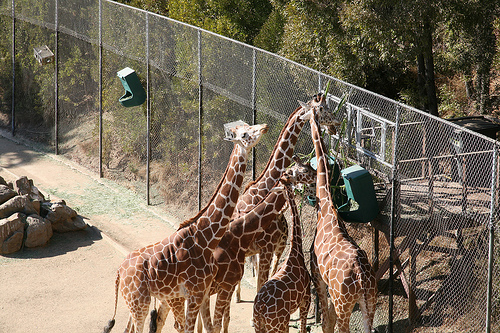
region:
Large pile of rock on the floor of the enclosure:
[0, 172, 97, 252]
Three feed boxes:
[116, 66, 385, 218]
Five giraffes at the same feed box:
[96, 86, 381, 329]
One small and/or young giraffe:
[247, 168, 317, 331]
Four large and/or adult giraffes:
[97, 89, 380, 331]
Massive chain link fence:
[1, 3, 498, 331]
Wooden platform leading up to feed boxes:
[363, 90, 497, 328]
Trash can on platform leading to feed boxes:
[446, 109, 496, 185]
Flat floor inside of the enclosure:
[1, 145, 204, 328]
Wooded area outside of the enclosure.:
[3, 4, 495, 130]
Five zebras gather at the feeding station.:
[200, 103, 370, 221]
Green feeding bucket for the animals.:
[110, 60, 148, 111]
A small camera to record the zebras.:
[30, 42, 70, 68]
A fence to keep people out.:
[138, 30, 203, 200]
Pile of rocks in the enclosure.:
[1, 175, 83, 256]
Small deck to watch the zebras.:
[395, 120, 491, 230]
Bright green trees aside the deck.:
[275, 10, 441, 55]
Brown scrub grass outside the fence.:
[153, 155, 189, 201]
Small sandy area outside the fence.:
[57, 107, 99, 150]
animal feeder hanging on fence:
[102, 58, 153, 113]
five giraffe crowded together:
[99, 91, 391, 319]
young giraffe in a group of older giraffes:
[253, 174, 311, 331]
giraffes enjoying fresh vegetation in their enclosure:
[205, 96, 423, 228]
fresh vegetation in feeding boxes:
[322, 88, 388, 216]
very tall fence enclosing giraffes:
[390, 127, 496, 327]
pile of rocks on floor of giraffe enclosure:
[1, 138, 107, 283]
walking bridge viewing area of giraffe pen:
[379, 85, 499, 242]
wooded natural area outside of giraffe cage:
[259, 9, 495, 99]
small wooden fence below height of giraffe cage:
[421, 220, 481, 332]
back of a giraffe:
[345, 235, 359, 257]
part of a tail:
[116, 304, 119, 314]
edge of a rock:
[63, 204, 78, 217]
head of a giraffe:
[304, 88, 331, 117]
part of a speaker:
[353, 178, 370, 194]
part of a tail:
[108, 293, 121, 314]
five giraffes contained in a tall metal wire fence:
[101, 89, 378, 331]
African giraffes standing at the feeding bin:
[102, 90, 379, 332]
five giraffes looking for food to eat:
[102, 91, 377, 331]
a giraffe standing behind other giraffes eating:
[100, 121, 270, 331]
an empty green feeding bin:
[115, 66, 148, 108]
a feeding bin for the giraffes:
[116, 66, 147, 108]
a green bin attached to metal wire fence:
[116, 65, 146, 107]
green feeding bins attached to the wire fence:
[305, 160, 381, 224]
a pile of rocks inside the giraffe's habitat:
[0, 173, 87, 256]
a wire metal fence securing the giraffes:
[0, 0, 498, 331]